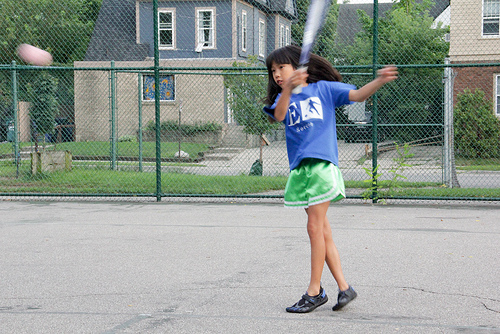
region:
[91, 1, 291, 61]
second story of house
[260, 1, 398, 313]
girl swinging baseball bat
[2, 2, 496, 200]
green poles on fence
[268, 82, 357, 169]
short sleeve blue shirt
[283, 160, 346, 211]
green shorts with white trim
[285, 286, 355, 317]
shoes on two feet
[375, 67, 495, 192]
section of chain link fence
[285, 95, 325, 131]
white emblem on shirt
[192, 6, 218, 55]
window with white curtain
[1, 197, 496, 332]
gray concrete surface under fence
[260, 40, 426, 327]
this is a girl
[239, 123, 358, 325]
this is a tennis player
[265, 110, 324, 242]
this is a pair of shorts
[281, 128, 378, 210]
the shorts are green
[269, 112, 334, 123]
this is a tee shirt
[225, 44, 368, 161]
the shirt is blue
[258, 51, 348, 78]
this is a racket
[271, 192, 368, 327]
this is a shoe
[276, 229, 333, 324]
the shoe is dark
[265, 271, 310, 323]
the shoe is black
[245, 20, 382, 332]
Girl with a bat.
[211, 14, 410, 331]
girl with a blue shirt.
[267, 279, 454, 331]
Black shoes on the woman.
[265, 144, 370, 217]
Green shorts on the girl.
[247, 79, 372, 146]
Logo on the shirt.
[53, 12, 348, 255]
House in the background.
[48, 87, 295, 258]
Grass by the fence.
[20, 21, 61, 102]
Ball in the air.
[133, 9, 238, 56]
Window on the building.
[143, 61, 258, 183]
Steps by the house.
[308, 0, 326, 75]
blue and black tennis racket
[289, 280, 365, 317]
black shoes on feet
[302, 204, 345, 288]
tan legs of girl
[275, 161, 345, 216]
green shorts on girl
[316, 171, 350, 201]
white stripe on shorts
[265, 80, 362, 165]
blue shirt on girl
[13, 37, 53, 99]
ball in the air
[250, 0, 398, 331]
girl swinging tennis racket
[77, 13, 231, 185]
green fence in background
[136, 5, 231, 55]
blue house in background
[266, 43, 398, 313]
A brown haired Asian girl in a blue and white shirt.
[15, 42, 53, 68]
A faded light red ball that was hit in the air.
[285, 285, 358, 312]
Black and blue toe shoes on a girl.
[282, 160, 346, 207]
Green and white shorts on a girl.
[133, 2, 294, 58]
Blue top of a house.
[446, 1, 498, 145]
A brick bottom and tan top house.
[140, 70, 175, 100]
A blue and orange curtain in a bottom window.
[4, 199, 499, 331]
The grey concrete ground all around a girl inside the fence.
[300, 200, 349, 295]
Bare legs of a girl.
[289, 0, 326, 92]
A blurry bat.